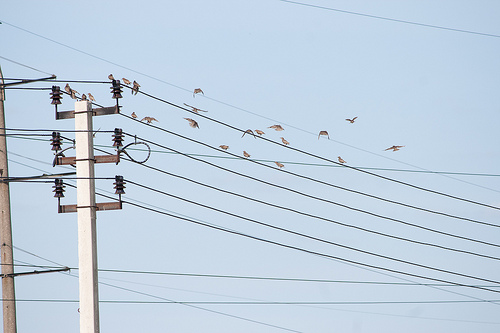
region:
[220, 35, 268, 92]
white clouds n blue sky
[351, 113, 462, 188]
white clouds n blue sky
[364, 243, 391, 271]
white clouds n blue sky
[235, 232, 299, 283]
white clouds n blue sky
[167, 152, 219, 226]
white clouds n blue sky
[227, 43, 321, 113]
white clouds n blue sky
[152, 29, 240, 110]
white clouds n blue sky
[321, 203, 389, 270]
white clouds n blue sky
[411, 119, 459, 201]
white clouds n blue sky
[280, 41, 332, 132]
white clouds n blue sky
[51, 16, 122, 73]
white clouds n blue sky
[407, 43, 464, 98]
white clouds n blue sky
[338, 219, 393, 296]
white clouds n blue sky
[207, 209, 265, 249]
white clouds n blue sky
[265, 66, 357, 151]
white clouds n blue sky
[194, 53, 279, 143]
white clouds n blue sky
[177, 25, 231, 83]
white clouds n blue sky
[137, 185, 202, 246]
white clouds n blue sky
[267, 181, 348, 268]
white clouds n blue sky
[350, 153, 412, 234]
white clouds n blue sky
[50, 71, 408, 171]
Flock of birds around power line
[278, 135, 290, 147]
Bird sitting on power line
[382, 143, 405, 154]
Bird flying with wings spread out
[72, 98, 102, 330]
White post supporting power lines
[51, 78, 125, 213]
Insulators for power lines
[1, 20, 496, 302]
Numerous power cables in sky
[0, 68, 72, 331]
Pylon with crossbars to support cables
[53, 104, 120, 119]
Crossbar holding insulators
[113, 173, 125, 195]
Single power line insulator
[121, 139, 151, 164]
Loop in cable attached to insulator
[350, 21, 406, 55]
white clouds in blue sky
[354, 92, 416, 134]
white clouds in blue sky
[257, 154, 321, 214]
white clouds in blue sky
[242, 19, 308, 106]
white clouds in blue sky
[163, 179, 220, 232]
white clouds in blue sky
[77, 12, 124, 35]
white clouds in blue sky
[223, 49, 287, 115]
white clouds in blue sky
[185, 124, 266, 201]
white clouds in blue sky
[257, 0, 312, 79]
white clouds in blue sky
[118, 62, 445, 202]
many birds on wires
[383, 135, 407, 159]
bird flying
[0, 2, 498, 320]
blue skies above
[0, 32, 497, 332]
many telephone wires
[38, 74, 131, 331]
white telephone pole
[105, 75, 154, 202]
many black circuits sticking out of pole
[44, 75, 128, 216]
many brackets on telephone pole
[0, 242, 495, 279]
telephone wire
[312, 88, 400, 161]
many birds flying and standing on phone wires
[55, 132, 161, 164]
wire overlapped on bracket in spiral